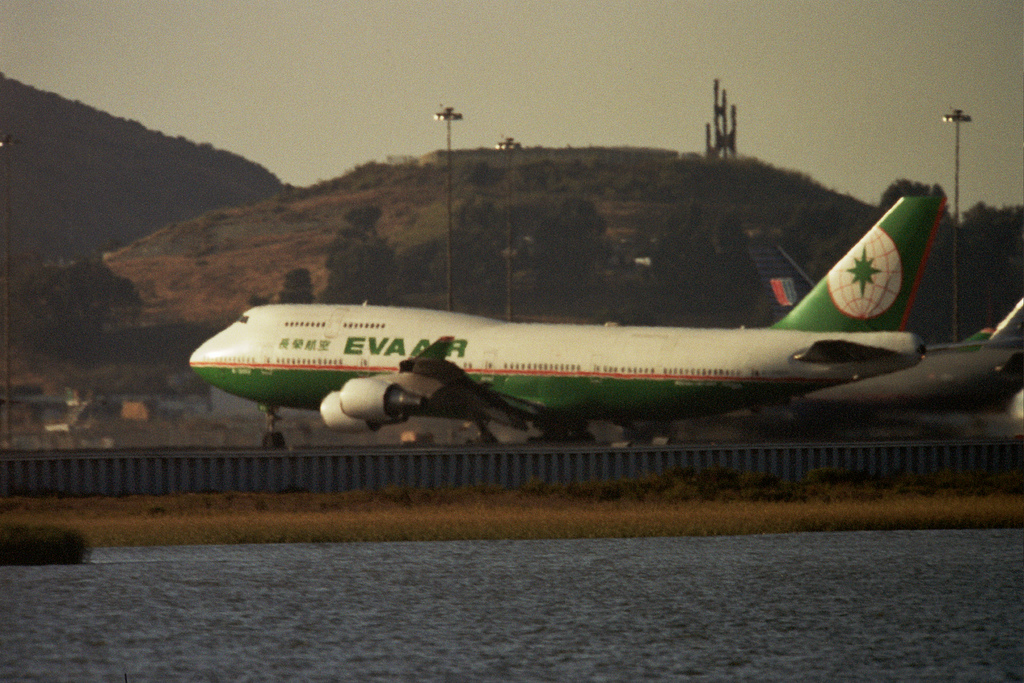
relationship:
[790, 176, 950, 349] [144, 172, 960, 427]
tail of plane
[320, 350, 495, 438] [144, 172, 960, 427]
wing on plane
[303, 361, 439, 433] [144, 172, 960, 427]
engine on plane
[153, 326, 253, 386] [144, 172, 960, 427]
nose on plane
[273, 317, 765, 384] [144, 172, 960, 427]
windows on plane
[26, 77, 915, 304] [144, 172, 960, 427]
hills behind plane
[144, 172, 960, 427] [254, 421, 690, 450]
plane has wheels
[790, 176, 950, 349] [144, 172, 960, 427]
tail on plane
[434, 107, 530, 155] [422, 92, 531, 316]
lights on pole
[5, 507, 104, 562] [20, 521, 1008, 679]
bush near water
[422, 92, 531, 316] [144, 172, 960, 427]
pole behind plane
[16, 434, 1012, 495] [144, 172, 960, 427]
gate near plane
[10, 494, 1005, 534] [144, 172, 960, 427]
grass near plane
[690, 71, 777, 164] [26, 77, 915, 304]
object on hills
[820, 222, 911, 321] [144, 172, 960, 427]
logo on plane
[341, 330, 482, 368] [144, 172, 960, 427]
letters on plane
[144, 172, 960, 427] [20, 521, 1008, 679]
plane near water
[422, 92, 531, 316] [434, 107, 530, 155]
pole with lights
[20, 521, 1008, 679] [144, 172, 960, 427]
water near plane